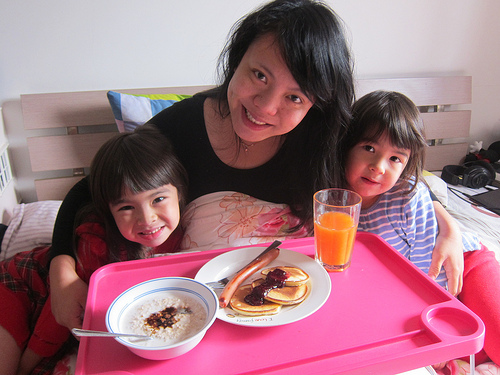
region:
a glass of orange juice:
[304, 186, 365, 271]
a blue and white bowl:
[102, 273, 217, 358]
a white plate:
[191, 243, 339, 328]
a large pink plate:
[72, 229, 484, 374]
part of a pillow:
[103, 89, 196, 131]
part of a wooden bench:
[21, 90, 118, 203]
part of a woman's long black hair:
[202, 1, 356, 233]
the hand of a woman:
[427, 233, 463, 298]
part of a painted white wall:
[363, 0, 498, 69]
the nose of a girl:
[135, 208, 159, 228]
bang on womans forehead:
[286, 27, 331, 73]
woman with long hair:
[304, 141, 333, 182]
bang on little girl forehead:
[381, 108, 404, 143]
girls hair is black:
[107, 156, 160, 174]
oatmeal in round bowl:
[138, 333, 187, 343]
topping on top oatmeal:
[149, 305, 179, 332]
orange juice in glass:
[320, 223, 352, 255]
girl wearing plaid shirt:
[396, 213, 433, 236]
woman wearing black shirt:
[168, 118, 193, 140]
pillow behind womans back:
[111, 92, 153, 119]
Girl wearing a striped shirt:
[338, 88, 470, 289]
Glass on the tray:
[304, 183, 367, 270]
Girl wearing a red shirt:
[0, 124, 183, 374]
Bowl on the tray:
[93, 277, 223, 372]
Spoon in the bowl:
[65, 321, 159, 348]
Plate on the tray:
[187, 228, 338, 336]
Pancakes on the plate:
[232, 261, 314, 317]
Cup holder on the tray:
[416, 286, 488, 351]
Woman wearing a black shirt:
[57, 12, 360, 278]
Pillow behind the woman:
[100, 71, 207, 138]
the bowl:
[206, 295, 223, 314]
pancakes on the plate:
[256, 268, 302, 301]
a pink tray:
[349, 288, 409, 337]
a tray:
[312, 330, 417, 360]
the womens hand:
[435, 223, 465, 288]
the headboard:
[25, 100, 74, 190]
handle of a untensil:
[67, 322, 119, 339]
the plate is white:
[272, 312, 296, 322]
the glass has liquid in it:
[318, 195, 355, 225]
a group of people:
[0, 5, 499, 372]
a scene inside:
[7, 0, 497, 368]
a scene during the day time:
[2, 5, 496, 373]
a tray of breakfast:
[40, 219, 491, 373]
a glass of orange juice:
[295, 171, 372, 281]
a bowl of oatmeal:
[89, 261, 236, 362]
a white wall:
[0, 2, 498, 210]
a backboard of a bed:
[9, 52, 494, 229]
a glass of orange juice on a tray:
[312, 188, 361, 273]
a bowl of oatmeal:
[106, 277, 218, 362]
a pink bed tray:
[74, 231, 486, 373]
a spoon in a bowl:
[69, 328, 150, 340]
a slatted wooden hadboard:
[19, 78, 471, 192]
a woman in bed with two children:
[46, 1, 471, 336]